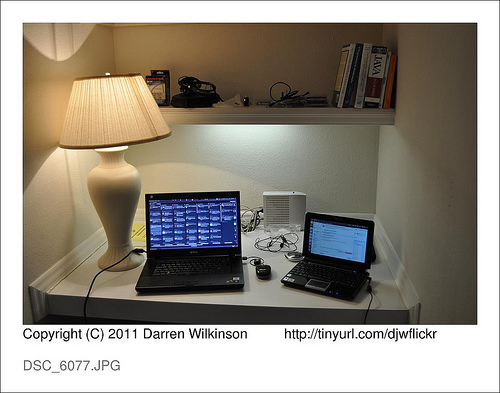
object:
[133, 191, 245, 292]
laptop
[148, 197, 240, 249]
screen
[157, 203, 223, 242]
display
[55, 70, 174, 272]
lamp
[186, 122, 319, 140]
light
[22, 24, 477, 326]
wall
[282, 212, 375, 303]
netbook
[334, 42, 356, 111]
book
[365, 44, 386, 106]
book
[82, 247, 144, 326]
cord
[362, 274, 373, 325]
cord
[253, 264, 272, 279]
mouse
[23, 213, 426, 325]
desk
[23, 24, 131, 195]
shade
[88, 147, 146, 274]
base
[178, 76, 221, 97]
headphone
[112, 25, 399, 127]
shelf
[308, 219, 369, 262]
screen